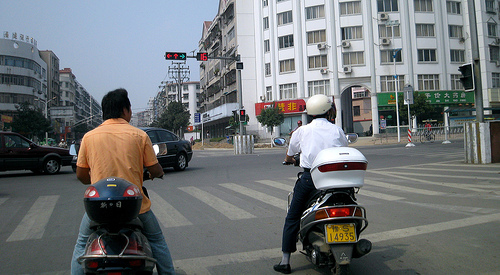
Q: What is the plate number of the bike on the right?
A: 14935.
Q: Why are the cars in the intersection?
A: They are turning.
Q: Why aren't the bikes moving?
A: They are stopped at an intersection.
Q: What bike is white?
A: The one on the right.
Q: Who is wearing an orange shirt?
A: The man on the left.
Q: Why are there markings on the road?
A: It's a crosswalk.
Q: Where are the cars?
A: In the intersection.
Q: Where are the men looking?
A: To their right.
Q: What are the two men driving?
A: Motorcycles.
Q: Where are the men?
A: Street intersection.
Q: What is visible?
A: Traffic light.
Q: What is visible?
A: A traffic light.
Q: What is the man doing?
A: Riding a moped.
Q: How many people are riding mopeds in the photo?
A: Two.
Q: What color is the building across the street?
A: White.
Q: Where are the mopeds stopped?
A: At the intersection.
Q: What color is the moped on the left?
A: Blue.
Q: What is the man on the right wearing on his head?
A: A helmet.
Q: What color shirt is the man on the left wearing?
A: Orange.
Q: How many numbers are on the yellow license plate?
A: Five.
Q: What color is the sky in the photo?
A: Blue.